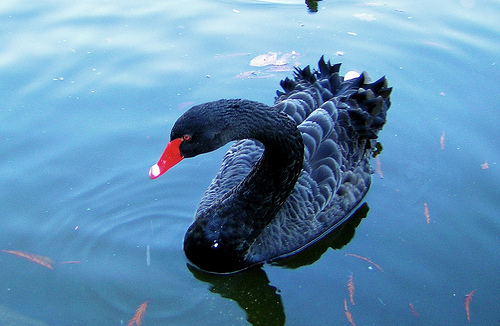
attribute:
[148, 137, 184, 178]
bill — red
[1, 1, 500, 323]
lake — white, blue, waves, black, feathered, pinky, light blue, calm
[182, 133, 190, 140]
eye — red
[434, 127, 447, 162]
orange fish — three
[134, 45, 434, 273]
swan — black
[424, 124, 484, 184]
fishes — little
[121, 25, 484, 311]
swan — large, white, red, peak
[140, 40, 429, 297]
swan — black, peak, white